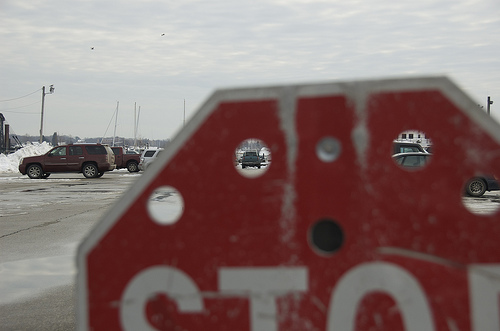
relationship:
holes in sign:
[121, 122, 498, 257] [77, 72, 500, 331]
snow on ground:
[1, 141, 56, 177] [1, 168, 498, 329]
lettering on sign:
[115, 262, 497, 327] [77, 72, 500, 331]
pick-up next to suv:
[101, 143, 145, 173] [16, 141, 119, 180]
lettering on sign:
[115, 262, 497, 327] [68, 66, 498, 328]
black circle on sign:
[301, 214, 348, 257] [77, 72, 500, 331]